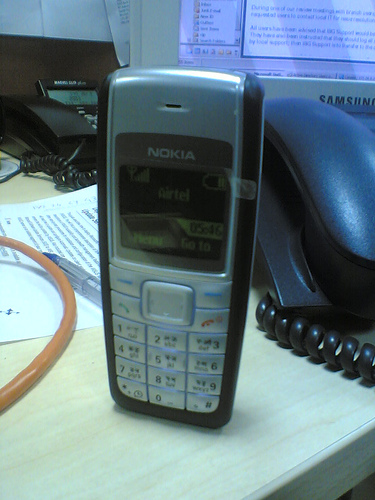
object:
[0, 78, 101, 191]
phone is black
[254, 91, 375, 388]
phone is black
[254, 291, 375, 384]
cord is black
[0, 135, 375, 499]
table is white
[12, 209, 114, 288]
notes on paper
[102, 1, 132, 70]
paper is on wall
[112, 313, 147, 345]
button on phone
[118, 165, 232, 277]
phone has screen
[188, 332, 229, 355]
button on phone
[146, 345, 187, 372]
button on phone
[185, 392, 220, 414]
button on phone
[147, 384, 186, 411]
button on phone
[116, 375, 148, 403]
button on phone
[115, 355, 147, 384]
button on phone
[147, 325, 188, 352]
button on phone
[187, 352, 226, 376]
button on phone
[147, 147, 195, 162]
phone is nokia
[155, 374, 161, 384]
number is on phone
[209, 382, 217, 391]
number is on phone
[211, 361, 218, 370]
phone has number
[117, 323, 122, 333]
phone has number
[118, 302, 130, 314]
symbol is green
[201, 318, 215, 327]
symbol is red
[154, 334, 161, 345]
number on phone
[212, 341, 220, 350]
number on phone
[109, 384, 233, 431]
case is black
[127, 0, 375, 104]
monitor is on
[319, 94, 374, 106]
monitor has logo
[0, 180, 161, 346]
paper is white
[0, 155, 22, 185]
dish is white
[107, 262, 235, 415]
phone has pad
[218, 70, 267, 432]
casing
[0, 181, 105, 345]
paper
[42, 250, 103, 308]
pen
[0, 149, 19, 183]
dish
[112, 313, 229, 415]
number pad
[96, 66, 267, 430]
cell phone